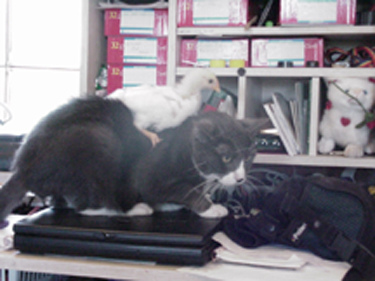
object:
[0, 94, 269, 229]
cat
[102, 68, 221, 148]
duck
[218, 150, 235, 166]
eye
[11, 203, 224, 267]
laptop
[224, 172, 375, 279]
backpack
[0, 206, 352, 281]
table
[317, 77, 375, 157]
bear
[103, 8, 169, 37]
boxes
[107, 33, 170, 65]
boxes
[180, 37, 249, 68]
boxes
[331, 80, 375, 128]
rose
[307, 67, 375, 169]
shelf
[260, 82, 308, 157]
papers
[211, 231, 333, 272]
notebook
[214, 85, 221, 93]
beak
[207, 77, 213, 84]
eye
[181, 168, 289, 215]
whiskers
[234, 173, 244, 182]
nose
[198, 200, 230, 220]
feet